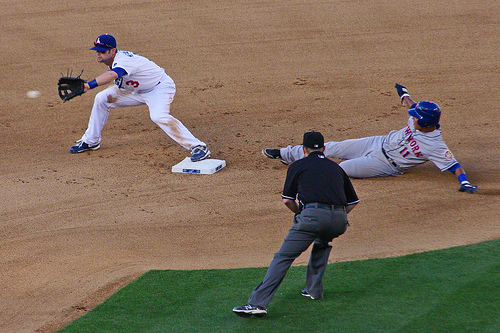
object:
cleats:
[67, 138, 101, 156]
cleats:
[187, 143, 211, 163]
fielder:
[56, 33, 211, 164]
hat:
[87, 32, 120, 55]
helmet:
[406, 101, 442, 130]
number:
[397, 149, 410, 160]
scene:
[0, 0, 499, 332]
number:
[123, 79, 141, 90]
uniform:
[78, 50, 208, 152]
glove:
[57, 83, 83, 105]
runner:
[259, 82, 478, 196]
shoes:
[261, 146, 293, 165]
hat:
[300, 129, 324, 151]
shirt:
[278, 151, 359, 207]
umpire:
[230, 130, 360, 319]